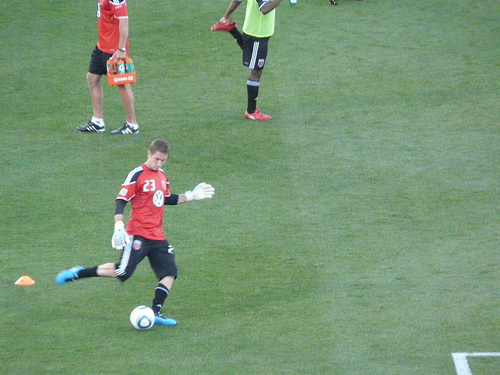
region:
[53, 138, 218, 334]
soccer player wearing a uniform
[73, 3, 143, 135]
soccer player wearing a uniform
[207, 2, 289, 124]
soccer player wearing a uniform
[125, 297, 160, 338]
blue and white soccer ball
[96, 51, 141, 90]
green and orange box of gatorade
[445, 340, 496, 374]
white lines painted on grass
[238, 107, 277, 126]
red and white cleats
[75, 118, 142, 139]
black and white cleats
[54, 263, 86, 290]
blue and black cleats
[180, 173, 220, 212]
large white glove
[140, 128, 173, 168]
head of a person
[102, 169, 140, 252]
arm of a person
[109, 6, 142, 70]
arm of a person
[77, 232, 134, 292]
leg of a person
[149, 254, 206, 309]
leg of a person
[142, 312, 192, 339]
feet of a person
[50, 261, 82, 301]
feet of a person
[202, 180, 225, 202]
hand of a person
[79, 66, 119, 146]
leg of a person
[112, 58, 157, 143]
leg of a person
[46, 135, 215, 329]
soccer player kicking a ball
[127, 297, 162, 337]
soccer ball on the field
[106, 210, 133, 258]
glove on soccer player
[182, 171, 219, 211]
glove on player's hand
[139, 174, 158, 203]
number on player's jersey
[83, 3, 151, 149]
man carrying gatorade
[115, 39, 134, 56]
watch on a wrist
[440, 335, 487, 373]
white line on the field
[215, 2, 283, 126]
soccer player stretching his leg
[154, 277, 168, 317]
sock on player's leg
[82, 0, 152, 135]
player carrying carton of drink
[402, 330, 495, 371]
white marking on soccer field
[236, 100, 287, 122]
red and white soccer shoe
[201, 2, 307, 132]
soccer player stretching his leg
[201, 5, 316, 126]
soccer player with green shirt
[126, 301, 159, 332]
a blue and white soccer ball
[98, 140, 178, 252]
soccer player with number 23 on uniform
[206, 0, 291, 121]
soccer player with leg in the air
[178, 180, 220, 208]
white soccer glove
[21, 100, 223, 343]
the man on the field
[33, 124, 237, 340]
the man kicking the ball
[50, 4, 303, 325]
the men playing soccer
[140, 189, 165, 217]
the logo on the shirt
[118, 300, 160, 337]
the ball on the field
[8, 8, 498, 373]
the field of grass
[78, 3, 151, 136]
the man carrying beverages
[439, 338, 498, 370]
white lines on the field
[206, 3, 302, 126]
the man is stretching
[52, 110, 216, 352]
the man wearing gloves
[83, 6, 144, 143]
A person holding a six pack of Gatorade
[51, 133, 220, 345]
A player about to kick the soccer ball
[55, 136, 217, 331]
a player wearing big white gloves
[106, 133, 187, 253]
A player wearing a red jersey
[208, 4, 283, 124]
A player standing on one leg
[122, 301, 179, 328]
A soccer ball by the foot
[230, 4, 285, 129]
A person wearing black shorts with a white stripe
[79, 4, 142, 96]
A guy wearing an orange jersey and black shorts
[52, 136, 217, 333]
A guy looking at the soccer ball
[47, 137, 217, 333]
A player attempting to kick the soccer ball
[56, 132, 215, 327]
The man about to kick the ball